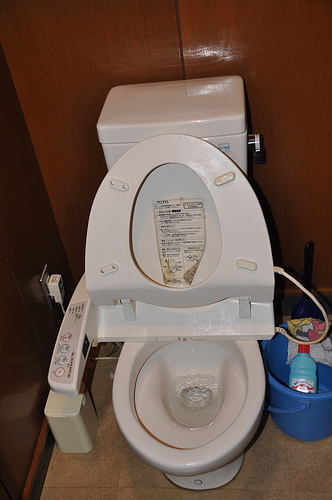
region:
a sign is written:
[50, 366, 75, 378]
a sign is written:
[53, 356, 72, 367]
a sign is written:
[57, 339, 70, 354]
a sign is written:
[58, 332, 77, 342]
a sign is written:
[55, 354, 73, 363]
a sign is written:
[77, 332, 100, 361]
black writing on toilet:
[65, 349, 77, 378]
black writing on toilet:
[65, 362, 70, 368]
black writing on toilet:
[80, 301, 86, 312]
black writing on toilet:
[77, 304, 81, 314]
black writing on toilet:
[75, 304, 77, 313]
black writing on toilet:
[70, 305, 74, 314]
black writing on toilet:
[66, 306, 71, 313]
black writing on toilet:
[154, 197, 167, 203]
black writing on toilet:
[180, 201, 202, 211]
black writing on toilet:
[161, 245, 180, 251]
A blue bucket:
[266, 314, 330, 461]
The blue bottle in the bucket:
[288, 340, 320, 395]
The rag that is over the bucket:
[288, 315, 331, 359]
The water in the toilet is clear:
[163, 366, 219, 424]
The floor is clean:
[47, 334, 329, 497]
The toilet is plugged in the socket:
[33, 260, 74, 305]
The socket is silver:
[36, 256, 63, 305]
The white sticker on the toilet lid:
[150, 192, 208, 297]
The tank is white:
[89, 75, 268, 207]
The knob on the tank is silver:
[250, 119, 269, 152]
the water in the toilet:
[172, 374, 223, 425]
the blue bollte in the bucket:
[293, 344, 317, 394]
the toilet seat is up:
[87, 153, 274, 342]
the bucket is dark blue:
[263, 327, 328, 441]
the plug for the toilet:
[42, 271, 64, 306]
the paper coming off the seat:
[152, 202, 201, 282]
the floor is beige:
[40, 357, 331, 495]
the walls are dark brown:
[4, 158, 330, 497]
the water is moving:
[175, 376, 215, 416]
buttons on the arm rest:
[55, 327, 77, 377]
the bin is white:
[40, 383, 98, 462]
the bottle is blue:
[288, 341, 311, 389]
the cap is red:
[294, 340, 304, 348]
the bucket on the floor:
[265, 378, 322, 453]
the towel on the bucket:
[285, 316, 329, 362]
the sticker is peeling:
[153, 194, 207, 286]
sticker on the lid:
[121, 162, 222, 288]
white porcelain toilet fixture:
[74, 68, 281, 495]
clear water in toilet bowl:
[165, 370, 224, 427]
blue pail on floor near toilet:
[259, 315, 331, 440]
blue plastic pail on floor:
[257, 316, 331, 442]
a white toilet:
[31, 63, 301, 496]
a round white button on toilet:
[190, 475, 209, 489]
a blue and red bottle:
[286, 337, 321, 393]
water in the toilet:
[158, 361, 221, 436]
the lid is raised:
[87, 129, 280, 486]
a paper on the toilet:
[150, 180, 207, 293]